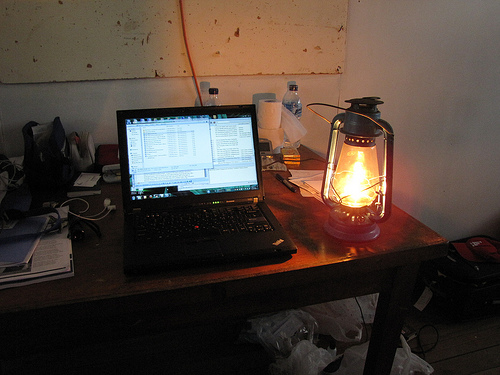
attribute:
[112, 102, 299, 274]
laptop — used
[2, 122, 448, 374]
desk — wood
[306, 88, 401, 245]
latern — lit